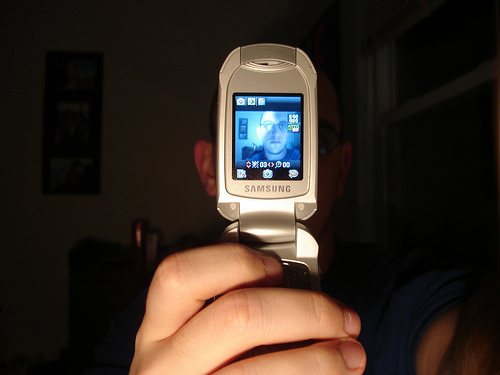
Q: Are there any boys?
A: No, there are no boys.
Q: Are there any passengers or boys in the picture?
A: No, there are no boys or passengers.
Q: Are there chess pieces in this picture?
A: No, there are no chess pieces.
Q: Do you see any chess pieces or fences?
A: No, there are no chess pieces or fences.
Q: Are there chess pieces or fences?
A: No, there are no chess pieces or fences.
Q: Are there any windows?
A: Yes, there is a window.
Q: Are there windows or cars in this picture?
A: Yes, there is a window.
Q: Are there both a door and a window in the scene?
A: No, there is a window but no doors.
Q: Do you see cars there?
A: No, there are no cars.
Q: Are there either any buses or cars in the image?
A: No, there are no cars or buses.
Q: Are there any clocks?
A: No, there are no clocks.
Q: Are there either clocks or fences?
A: No, there are no clocks or fences.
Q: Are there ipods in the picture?
A: No, there are no ipods.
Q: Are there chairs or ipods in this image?
A: No, there are no ipods or chairs.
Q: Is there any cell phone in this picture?
A: Yes, there is a cell phone.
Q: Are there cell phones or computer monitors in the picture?
A: Yes, there is a cell phone.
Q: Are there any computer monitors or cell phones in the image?
A: Yes, there is a cell phone.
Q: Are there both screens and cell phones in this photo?
A: Yes, there are both a cell phone and a screen.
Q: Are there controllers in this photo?
A: No, there are no controllers.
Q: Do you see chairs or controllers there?
A: No, there are no controllers or chairs.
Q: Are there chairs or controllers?
A: No, there are no controllers or chairs.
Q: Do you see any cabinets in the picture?
A: Yes, there is a cabinet.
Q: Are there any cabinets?
A: Yes, there is a cabinet.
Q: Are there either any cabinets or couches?
A: Yes, there is a cabinet.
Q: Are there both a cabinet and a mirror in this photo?
A: No, there is a cabinet but no mirrors.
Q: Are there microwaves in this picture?
A: No, there are no microwaves.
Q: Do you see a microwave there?
A: No, there are no microwaves.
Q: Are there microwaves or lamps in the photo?
A: No, there are no microwaves or lamps.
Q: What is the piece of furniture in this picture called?
A: The piece of furniture is a cabinet.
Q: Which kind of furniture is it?
A: The piece of furniture is a cabinet.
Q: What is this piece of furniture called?
A: This is a cabinet.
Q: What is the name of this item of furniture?
A: This is a cabinet.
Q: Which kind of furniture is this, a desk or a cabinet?
A: This is a cabinet.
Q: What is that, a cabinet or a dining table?
A: That is a cabinet.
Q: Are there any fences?
A: No, there are no fences.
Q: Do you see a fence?
A: No, there are no fences.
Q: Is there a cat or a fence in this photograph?
A: No, there are no fences or cats.